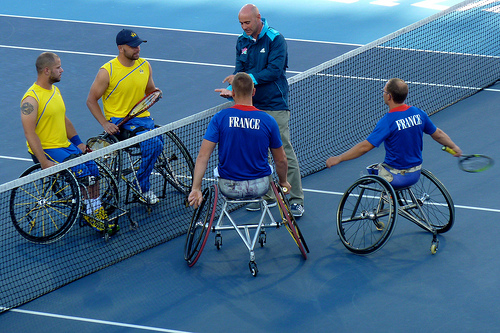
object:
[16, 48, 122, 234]
man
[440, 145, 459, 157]
handle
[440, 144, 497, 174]
racket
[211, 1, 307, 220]
man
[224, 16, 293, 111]
jacket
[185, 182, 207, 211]
side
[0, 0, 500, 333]
court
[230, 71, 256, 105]
head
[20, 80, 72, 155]
shirt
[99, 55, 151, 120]
shirt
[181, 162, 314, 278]
wheel chair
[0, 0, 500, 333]
ground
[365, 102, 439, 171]
blue shirt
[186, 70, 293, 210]
man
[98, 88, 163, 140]
racket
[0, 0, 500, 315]
net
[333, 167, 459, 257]
wheel chairs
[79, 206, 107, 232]
sneaker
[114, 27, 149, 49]
hat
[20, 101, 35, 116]
tattoo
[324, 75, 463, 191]
man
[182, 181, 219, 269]
tire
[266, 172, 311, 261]
tire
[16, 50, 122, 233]
fellow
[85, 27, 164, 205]
fellow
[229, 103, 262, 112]
trim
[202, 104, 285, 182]
shirts